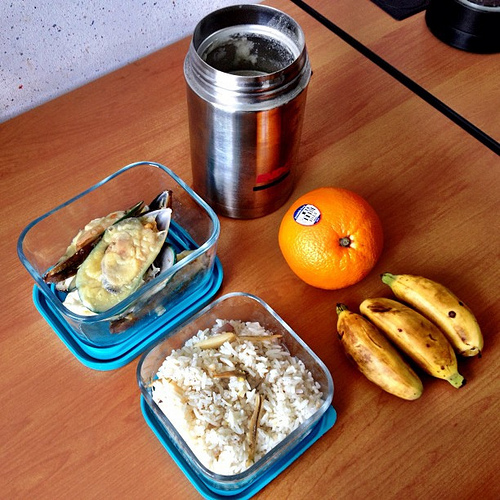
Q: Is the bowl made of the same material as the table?
A: No, the bowl is made of glass and the table is made of wood.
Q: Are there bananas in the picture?
A: Yes, there are bananas.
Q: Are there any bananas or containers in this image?
A: Yes, there are bananas.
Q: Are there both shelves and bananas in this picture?
A: No, there are bananas but no shelves.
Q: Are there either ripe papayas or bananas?
A: Yes, there are ripe bananas.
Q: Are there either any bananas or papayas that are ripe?
A: Yes, the bananas are ripe.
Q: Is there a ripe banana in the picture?
A: Yes, there are ripe bananas.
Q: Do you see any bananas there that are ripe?
A: Yes, there are bananas that are ripe.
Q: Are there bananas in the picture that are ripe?
A: Yes, there are bananas that are ripe.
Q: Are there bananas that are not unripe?
A: Yes, there are ripe bananas.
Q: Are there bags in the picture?
A: No, there are no bags.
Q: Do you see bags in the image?
A: No, there are no bags.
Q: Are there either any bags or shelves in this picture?
A: No, there are no bags or shelves.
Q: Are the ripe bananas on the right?
A: Yes, the bananas are on the right of the image.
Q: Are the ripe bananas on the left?
A: No, the bananas are on the right of the image.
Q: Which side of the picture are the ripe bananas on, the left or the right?
A: The bananas are on the right of the image.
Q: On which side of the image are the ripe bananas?
A: The bananas are on the right of the image.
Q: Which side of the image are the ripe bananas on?
A: The bananas are on the right of the image.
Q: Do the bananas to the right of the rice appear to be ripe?
A: Yes, the bananas are ripe.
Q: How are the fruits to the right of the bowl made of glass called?
A: The fruits are bananas.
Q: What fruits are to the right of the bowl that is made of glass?
A: The fruits are bananas.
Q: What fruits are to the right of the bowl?
A: The fruits are bananas.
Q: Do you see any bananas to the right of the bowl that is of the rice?
A: Yes, there are bananas to the right of the bowl.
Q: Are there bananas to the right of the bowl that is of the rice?
A: Yes, there are bananas to the right of the bowl.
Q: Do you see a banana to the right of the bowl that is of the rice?
A: Yes, there are bananas to the right of the bowl.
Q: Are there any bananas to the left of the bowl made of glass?
A: No, the bananas are to the right of the bowl.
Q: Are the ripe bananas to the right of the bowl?
A: Yes, the bananas are to the right of the bowl.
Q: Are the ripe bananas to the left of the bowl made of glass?
A: No, the bananas are to the right of the bowl.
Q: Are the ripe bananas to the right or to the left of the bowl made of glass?
A: The bananas are to the right of the bowl.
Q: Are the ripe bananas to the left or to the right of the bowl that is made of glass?
A: The bananas are to the right of the bowl.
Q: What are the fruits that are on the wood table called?
A: The fruits are bananas.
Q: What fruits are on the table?
A: The fruits are bananas.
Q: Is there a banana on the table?
A: Yes, there are bananas on the table.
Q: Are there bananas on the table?
A: Yes, there are bananas on the table.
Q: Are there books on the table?
A: No, there are bananas on the table.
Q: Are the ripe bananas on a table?
A: Yes, the bananas are on a table.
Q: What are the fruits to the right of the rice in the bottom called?
A: The fruits are bananas.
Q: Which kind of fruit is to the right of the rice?
A: The fruits are bananas.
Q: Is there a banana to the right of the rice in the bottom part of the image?
A: Yes, there are bananas to the right of the rice.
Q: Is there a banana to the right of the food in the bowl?
A: Yes, there are bananas to the right of the rice.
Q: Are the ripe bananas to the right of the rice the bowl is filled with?
A: Yes, the bananas are to the right of the rice.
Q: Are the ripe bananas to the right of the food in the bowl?
A: Yes, the bananas are to the right of the rice.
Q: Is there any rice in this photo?
A: Yes, there is rice.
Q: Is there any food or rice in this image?
A: Yes, there is rice.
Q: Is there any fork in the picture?
A: No, there are no forks.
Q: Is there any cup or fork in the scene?
A: No, there are no forks or cups.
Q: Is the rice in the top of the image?
A: No, the rice is in the bottom of the image.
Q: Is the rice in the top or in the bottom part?
A: The rice is in the bottom of the image.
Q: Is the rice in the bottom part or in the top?
A: The rice is in the bottom of the image.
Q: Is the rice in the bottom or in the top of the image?
A: The rice is in the bottom of the image.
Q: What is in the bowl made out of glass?
A: The rice is in the bowl.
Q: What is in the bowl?
A: The rice is in the bowl.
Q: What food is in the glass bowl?
A: The food is rice.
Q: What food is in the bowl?
A: The food is rice.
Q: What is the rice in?
A: The rice is in the bowl.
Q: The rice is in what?
A: The rice is in the bowl.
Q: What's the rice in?
A: The rice is in the bowl.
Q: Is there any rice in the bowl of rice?
A: Yes, there is rice in the bowl.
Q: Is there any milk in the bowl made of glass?
A: No, there is rice in the bowl.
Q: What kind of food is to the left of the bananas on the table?
A: The food is rice.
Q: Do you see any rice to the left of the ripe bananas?
A: Yes, there is rice to the left of the bananas.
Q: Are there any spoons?
A: No, there are no spoons.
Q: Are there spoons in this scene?
A: No, there are no spoons.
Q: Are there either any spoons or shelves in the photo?
A: No, there are no spoons or shelves.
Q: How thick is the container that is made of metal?
A: The container is thick.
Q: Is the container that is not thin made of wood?
A: No, the container is made of metal.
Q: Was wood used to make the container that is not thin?
A: No, the container is made of metal.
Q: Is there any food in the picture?
A: Yes, there is food.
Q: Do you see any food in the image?
A: Yes, there is food.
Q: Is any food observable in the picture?
A: Yes, there is food.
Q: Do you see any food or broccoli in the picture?
A: Yes, there is food.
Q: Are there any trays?
A: No, there are no trays.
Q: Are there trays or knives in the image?
A: No, there are no trays or knives.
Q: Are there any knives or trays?
A: No, there are no trays or knives.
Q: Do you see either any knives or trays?
A: No, there are no trays or knives.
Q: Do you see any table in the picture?
A: Yes, there is a table.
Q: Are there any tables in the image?
A: Yes, there is a table.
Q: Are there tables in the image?
A: Yes, there is a table.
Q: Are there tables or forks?
A: Yes, there is a table.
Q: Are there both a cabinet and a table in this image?
A: No, there is a table but no cabinets.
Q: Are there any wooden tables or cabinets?
A: Yes, there is a wood table.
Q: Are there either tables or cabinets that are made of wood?
A: Yes, the table is made of wood.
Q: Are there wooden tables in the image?
A: Yes, there is a wood table.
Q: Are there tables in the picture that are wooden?
A: Yes, there is a table that is wooden.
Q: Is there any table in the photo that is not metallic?
A: Yes, there is a wooden table.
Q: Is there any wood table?
A: Yes, there is a table that is made of wood.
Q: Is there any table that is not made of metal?
A: Yes, there is a table that is made of wood.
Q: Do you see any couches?
A: No, there are no couches.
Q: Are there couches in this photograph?
A: No, there are no couches.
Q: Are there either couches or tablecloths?
A: No, there are no couches or tablecloths.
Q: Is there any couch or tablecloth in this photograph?
A: No, there are no couches or tablecloths.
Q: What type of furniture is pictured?
A: The furniture is a table.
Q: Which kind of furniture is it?
A: The piece of furniture is a table.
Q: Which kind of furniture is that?
A: That is a table.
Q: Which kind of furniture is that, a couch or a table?
A: That is a table.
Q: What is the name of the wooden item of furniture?
A: The piece of furniture is a table.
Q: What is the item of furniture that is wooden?
A: The piece of furniture is a table.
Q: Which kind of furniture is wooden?
A: The furniture is a table.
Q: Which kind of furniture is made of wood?
A: The furniture is a table.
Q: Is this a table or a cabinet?
A: This is a table.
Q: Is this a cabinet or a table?
A: This is a table.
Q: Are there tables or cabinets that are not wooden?
A: No, there is a table but it is wooden.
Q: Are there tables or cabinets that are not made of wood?
A: No, there is a table but it is made of wood.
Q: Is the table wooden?
A: Yes, the table is wooden.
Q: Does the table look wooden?
A: Yes, the table is wooden.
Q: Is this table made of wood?
A: Yes, the table is made of wood.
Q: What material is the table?
A: The table is made of wood.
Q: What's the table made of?
A: The table is made of wood.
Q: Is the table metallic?
A: No, the table is wooden.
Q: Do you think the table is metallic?
A: No, the table is wooden.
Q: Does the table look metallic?
A: No, the table is wooden.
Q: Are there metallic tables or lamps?
A: No, there is a table but it is wooden.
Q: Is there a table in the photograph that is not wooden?
A: No, there is a table but it is wooden.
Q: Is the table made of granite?
A: No, the table is made of wood.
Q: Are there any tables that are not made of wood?
A: No, there is a table but it is made of wood.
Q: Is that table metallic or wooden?
A: The table is wooden.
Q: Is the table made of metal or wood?
A: The table is made of wood.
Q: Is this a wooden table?
A: Yes, this is a wooden table.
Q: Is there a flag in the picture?
A: No, there are no flags.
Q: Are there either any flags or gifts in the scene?
A: No, there are no flags or gifts.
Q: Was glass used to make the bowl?
A: Yes, the bowl is made of glass.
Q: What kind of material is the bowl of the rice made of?
A: The bowl is made of glass.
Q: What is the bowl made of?
A: The bowl is made of glass.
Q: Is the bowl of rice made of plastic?
A: No, the bowl is made of glass.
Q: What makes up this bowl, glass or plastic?
A: The bowl is made of glass.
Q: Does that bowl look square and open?
A: Yes, the bowl is square and open.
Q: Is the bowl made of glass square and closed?
A: No, the bowl is square but open.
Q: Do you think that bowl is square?
A: Yes, the bowl is square.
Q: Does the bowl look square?
A: Yes, the bowl is square.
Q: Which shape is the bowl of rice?
A: The bowl is square.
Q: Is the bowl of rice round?
A: No, the bowl is square.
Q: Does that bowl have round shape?
A: No, the bowl is square.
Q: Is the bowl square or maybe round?
A: The bowl is square.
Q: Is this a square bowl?
A: Yes, this is a square bowl.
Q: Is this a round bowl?
A: No, this is a square bowl.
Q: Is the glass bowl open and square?
A: Yes, the bowl is open and square.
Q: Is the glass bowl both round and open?
A: No, the bowl is open but square.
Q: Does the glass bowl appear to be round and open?
A: No, the bowl is open but square.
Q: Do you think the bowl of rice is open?
A: Yes, the bowl is open.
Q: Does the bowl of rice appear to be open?
A: Yes, the bowl is open.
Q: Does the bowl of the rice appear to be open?
A: Yes, the bowl is open.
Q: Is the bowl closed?
A: No, the bowl is open.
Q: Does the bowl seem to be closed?
A: No, the bowl is open.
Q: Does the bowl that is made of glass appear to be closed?
A: No, the bowl is open.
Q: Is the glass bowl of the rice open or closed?
A: The bowl is open.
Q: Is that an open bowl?
A: Yes, that is an open bowl.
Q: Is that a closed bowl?
A: No, that is an open bowl.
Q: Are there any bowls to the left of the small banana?
A: Yes, there is a bowl to the left of the banana.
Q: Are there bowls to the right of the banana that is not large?
A: No, the bowl is to the left of the banana.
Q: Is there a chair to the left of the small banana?
A: No, there is a bowl to the left of the banana.